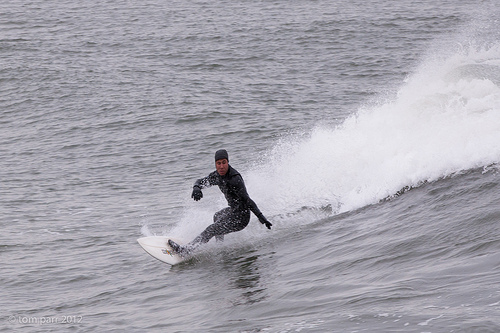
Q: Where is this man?
A: In the ocean.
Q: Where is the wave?
A: In the ocean.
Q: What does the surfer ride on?
A: A wave.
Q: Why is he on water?
A: He is surfing.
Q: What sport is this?
A: Surfing.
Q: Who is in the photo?
A: A man.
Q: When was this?
A: Daytime.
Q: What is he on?
A: A surfboard.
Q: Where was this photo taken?
A: In the ocean.